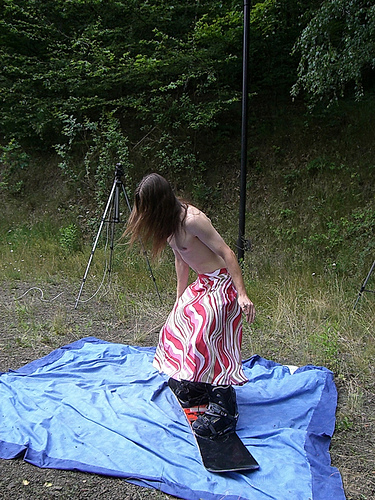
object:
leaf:
[119, 140, 123, 145]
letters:
[189, 405, 207, 412]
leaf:
[166, 81, 177, 89]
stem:
[183, 77, 216, 97]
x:
[74, 152, 163, 312]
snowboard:
[167, 375, 260, 473]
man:
[120, 171, 256, 386]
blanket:
[5, 332, 369, 494]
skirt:
[152, 272, 244, 379]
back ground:
[42, 358, 139, 450]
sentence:
[238, 76, 251, 163]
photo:
[4, 4, 373, 499]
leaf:
[98, 162, 109, 177]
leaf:
[97, 143, 106, 151]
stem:
[130, 120, 162, 139]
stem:
[98, 106, 110, 139]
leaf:
[110, 126, 113, 128]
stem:
[112, 128, 123, 147]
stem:
[93, 151, 98, 165]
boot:
[192, 385, 240, 442]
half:
[151, 271, 257, 386]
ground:
[330, 433, 372, 494]